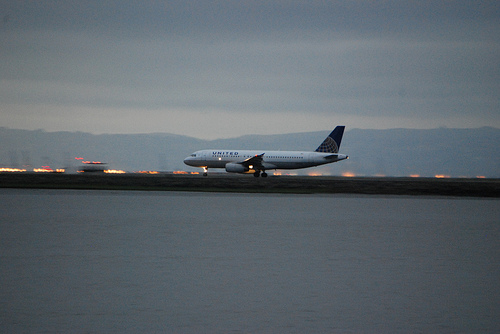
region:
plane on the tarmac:
[174, 126, 362, 186]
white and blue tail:
[313, 120, 346, 155]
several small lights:
[1, 163, 496, 183]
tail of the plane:
[304, 112, 357, 182]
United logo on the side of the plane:
[209, 149, 241, 156]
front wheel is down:
[201, 161, 207, 175]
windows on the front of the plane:
[185, 150, 202, 160]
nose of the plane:
[181, 154, 190, 166]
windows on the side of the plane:
[206, 151, 256, 159]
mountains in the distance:
[3, 119, 498, 171]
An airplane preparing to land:
[182, 124, 352, 178]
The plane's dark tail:
[317, 122, 347, 155]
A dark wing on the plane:
[238, 151, 266, 171]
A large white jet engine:
[225, 161, 245, 173]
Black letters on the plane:
[210, 149, 239, 157]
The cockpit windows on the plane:
[190, 151, 198, 159]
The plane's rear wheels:
[254, 167, 268, 178]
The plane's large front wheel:
[202, 165, 212, 179]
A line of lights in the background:
[0, 166, 499, 181]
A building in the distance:
[77, 161, 109, 173]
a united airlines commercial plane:
[180, 134, 361, 191]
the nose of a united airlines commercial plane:
[178, 149, 205, 168]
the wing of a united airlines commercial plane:
[236, 152, 263, 175]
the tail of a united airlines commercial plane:
[316, 122, 350, 173]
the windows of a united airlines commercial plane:
[274, 149, 306, 168]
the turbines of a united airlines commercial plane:
[217, 149, 259, 178]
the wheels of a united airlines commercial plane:
[250, 173, 270, 180]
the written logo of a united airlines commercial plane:
[203, 141, 240, 160]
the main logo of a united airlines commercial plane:
[306, 123, 353, 153]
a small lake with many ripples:
[98, 209, 263, 309]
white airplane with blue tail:
[175, 118, 353, 189]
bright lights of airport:
[6, 155, 67, 179]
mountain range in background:
[8, 125, 373, 156]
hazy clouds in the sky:
[261, 59, 359, 119]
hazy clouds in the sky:
[171, 14, 234, 114]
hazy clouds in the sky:
[31, 18, 116, 91]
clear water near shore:
[86, 225, 159, 291]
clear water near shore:
[196, 256, 296, 328]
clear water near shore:
[288, 199, 350, 256]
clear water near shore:
[387, 189, 431, 284]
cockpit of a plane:
[177, 145, 204, 168]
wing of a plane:
[228, 152, 265, 178]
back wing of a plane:
[307, 108, 358, 180]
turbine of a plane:
[217, 155, 246, 175]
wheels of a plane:
[187, 169, 281, 179]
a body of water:
[143, 217, 445, 307]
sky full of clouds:
[104, 21, 367, 123]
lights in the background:
[25, 152, 170, 191]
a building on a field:
[65, 150, 116, 180]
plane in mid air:
[157, 99, 373, 201]